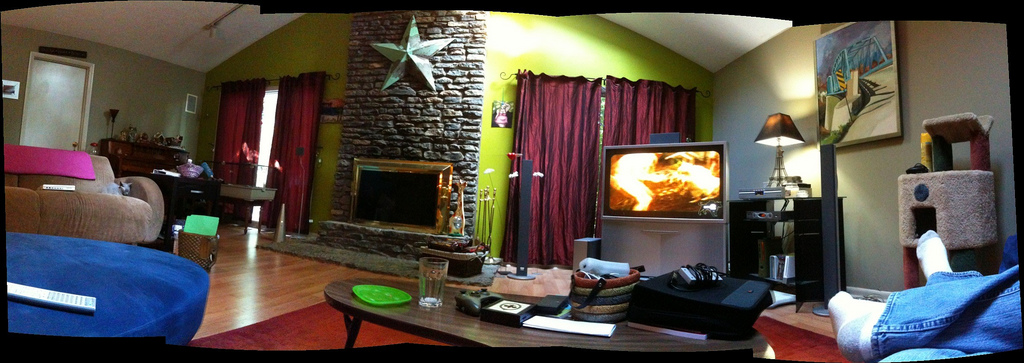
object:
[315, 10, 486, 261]
fireplace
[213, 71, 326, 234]
curtain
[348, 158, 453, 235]
fireplace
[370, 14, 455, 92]
bronze star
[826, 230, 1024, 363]
person's legs/feet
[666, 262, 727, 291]
grey/black controller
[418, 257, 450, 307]
clear glass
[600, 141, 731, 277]
television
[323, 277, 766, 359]
coffee table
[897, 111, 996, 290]
cat house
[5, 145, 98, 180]
blanket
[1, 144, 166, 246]
couch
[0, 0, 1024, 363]
living room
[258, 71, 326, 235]
drapes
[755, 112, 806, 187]
lamp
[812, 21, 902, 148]
painting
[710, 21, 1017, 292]
wall